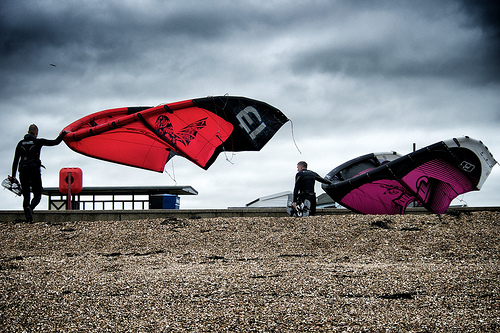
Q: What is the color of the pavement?
A: Brown.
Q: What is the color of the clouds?
A: Grey.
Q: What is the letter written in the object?
A: EI.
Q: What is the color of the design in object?
A: Black.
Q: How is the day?
A: Cloudy.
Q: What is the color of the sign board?
A: Red.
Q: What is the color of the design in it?
A: Black.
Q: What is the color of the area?
A: Brown.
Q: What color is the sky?
A: Gray white and blue.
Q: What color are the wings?
A: Red and black.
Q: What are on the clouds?
A: Black gray color.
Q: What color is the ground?
A: Light brown.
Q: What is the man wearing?
A: A wet suit.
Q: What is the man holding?
A: Red wings.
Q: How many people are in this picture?
A: 2.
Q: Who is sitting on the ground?
A: A man.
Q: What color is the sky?
A: Gray.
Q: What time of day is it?
A: Dusk.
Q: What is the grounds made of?
A: Pebbles.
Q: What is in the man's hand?
A: Parachute.